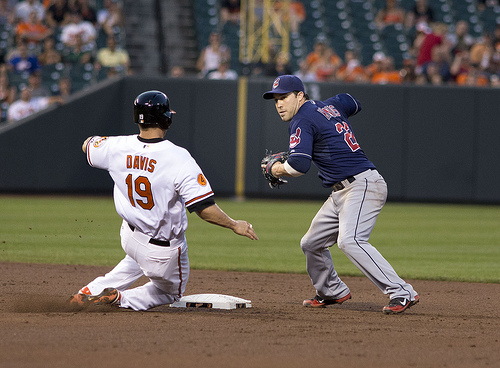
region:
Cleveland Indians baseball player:
[259, 72, 420, 313]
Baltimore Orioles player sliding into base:
[68, 88, 258, 312]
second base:
[168, 293, 251, 310]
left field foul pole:
[233, 0, 288, 203]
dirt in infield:
[1, 260, 499, 367]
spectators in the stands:
[0, 1, 499, 128]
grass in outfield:
[0, 194, 498, 282]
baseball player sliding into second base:
[61, 89, 257, 314]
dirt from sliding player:
[10, 296, 122, 312]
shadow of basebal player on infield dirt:
[146, 304, 298, 321]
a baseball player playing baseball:
[65, 90, 260, 322]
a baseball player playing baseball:
[255, 69, 427, 321]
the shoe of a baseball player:
[290, 280, 352, 313]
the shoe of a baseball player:
[382, 289, 422, 313]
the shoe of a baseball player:
[62, 287, 122, 309]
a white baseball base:
[161, 283, 254, 315]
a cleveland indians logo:
[280, 126, 308, 153]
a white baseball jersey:
[84, 127, 217, 246]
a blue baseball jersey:
[263, 89, 383, 198]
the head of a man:
[257, 71, 312, 124]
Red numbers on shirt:
[125, 174, 154, 213]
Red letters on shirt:
[125, 154, 157, 174]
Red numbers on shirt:
[333, 120, 359, 152]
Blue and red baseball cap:
[260, 74, 305, 100]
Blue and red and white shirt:
[285, 90, 378, 188]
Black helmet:
[130, 89, 177, 129]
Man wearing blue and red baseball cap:
[257, 73, 420, 313]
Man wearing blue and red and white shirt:
[253, 72, 422, 317]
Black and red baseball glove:
[259, 148, 290, 189]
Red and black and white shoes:
[382, 292, 421, 314]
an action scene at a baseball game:
[26, 15, 461, 329]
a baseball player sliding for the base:
[68, 65, 255, 351]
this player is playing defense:
[244, 59, 425, 339]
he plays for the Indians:
[246, 63, 431, 325]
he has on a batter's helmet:
[110, 87, 184, 147]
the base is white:
[160, 273, 255, 321]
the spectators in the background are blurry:
[14, 4, 490, 81]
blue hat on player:
[260, 73, 300, 96]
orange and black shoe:
[384, 291, 418, 313]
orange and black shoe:
[301, 291, 351, 307]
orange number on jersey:
[126, 170, 151, 207]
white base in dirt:
[167, 290, 249, 310]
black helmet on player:
[132, 87, 171, 124]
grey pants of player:
[298, 179, 408, 299]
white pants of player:
[84, 234, 181, 310]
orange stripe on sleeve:
[184, 187, 212, 207]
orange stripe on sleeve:
[86, 135, 91, 167]